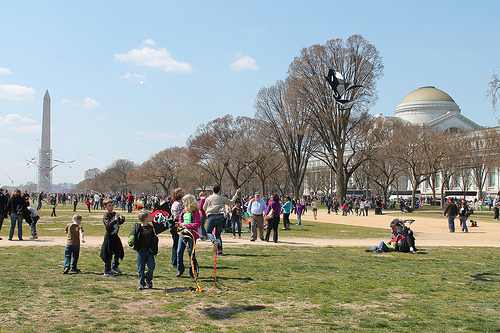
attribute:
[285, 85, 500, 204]
building — distant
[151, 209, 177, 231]
kite — black, white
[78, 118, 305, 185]
trees — brown, tall, thin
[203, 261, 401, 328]
grass — green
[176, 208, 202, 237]
sweater — pink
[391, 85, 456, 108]
dome — gray, large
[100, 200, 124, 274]
kid — playing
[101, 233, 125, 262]
jacket — tied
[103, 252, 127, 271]
jeans — blue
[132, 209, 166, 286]
kid — playing, walking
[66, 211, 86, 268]
kid — playing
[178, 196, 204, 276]
kid — playing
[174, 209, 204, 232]
jacket — pink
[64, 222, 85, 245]
shirt — on, brown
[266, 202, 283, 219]
shirt — purple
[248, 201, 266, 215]
shirt — green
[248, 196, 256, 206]
bag — red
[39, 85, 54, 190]
monument — long, oblong